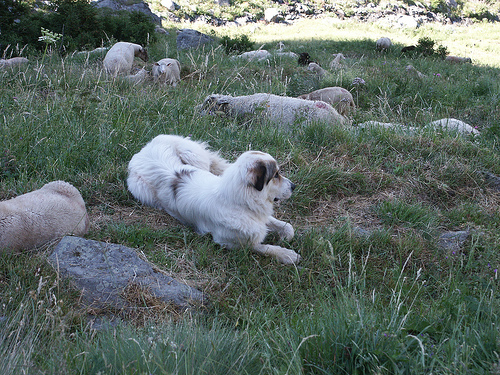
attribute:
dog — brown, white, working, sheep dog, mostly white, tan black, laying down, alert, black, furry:
[127, 132, 302, 268]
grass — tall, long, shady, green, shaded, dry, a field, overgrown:
[0, 19, 498, 374]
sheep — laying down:
[197, 93, 352, 141]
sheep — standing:
[101, 41, 150, 77]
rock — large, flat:
[47, 233, 208, 315]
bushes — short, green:
[1, 0, 161, 61]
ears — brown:
[245, 157, 266, 192]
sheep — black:
[296, 51, 319, 67]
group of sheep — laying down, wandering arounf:
[0, 37, 483, 149]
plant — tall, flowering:
[36, 25, 65, 78]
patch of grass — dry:
[307, 190, 426, 244]